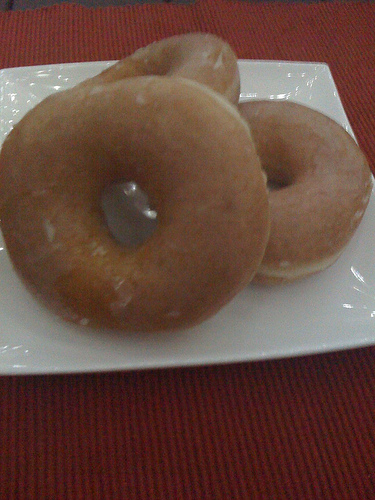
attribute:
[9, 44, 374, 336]
doughnuts — faced, glazed, three, stacked, flat, touching, square, white, round, brown, centered, upright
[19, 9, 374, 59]
mat — wrippled, striped, lined, red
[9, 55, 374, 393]
plate — reflected, shining, sitting, glass, square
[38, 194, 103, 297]
glaze — white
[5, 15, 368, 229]
table — red